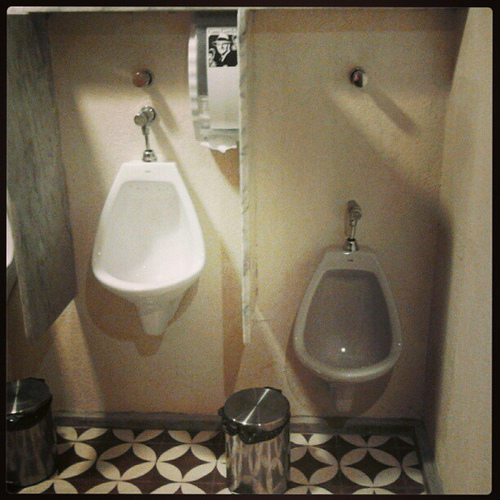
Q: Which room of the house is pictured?
A: It is a bathroom.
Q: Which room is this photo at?
A: It is at the bathroom.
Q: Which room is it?
A: It is a bathroom.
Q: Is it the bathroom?
A: Yes, it is the bathroom.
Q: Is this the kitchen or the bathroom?
A: It is the bathroom.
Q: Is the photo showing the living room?
A: No, the picture is showing the bathroom.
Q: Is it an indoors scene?
A: Yes, it is indoors.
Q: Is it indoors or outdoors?
A: It is indoors.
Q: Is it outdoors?
A: No, it is indoors.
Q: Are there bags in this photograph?
A: Yes, there is a bag.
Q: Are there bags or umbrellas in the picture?
A: Yes, there is a bag.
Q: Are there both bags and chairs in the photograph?
A: No, there is a bag but no chairs.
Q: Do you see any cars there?
A: No, there are no cars.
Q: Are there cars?
A: No, there are no cars.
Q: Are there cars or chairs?
A: No, there are no cars or chairs.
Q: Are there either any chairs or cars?
A: No, there are no cars or chairs.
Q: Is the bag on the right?
A: No, the bag is on the left of the image.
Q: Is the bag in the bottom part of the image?
A: Yes, the bag is in the bottom of the image.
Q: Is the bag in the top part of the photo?
A: No, the bag is in the bottom of the image.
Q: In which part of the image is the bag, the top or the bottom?
A: The bag is in the bottom of the image.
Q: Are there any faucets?
A: No, there are no faucets.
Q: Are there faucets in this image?
A: No, there are no faucets.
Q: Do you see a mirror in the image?
A: No, there are no mirrors.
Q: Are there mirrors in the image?
A: No, there are no mirrors.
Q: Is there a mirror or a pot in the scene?
A: No, there are no mirrors or pots.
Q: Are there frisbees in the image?
A: No, there are no frisbees.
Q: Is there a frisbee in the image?
A: No, there are no frisbees.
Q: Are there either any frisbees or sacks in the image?
A: No, there are no frisbees or sacks.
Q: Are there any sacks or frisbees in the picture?
A: No, there are no frisbees or sacks.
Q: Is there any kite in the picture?
A: No, there are no kites.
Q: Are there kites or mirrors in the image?
A: No, there are no kites or mirrors.